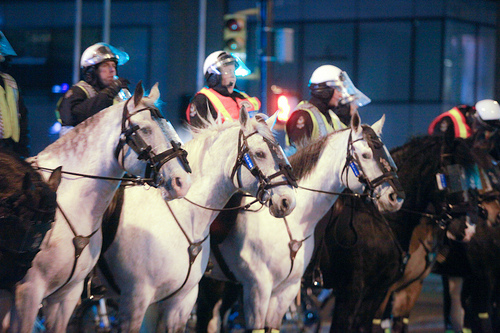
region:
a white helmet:
[78, 40, 133, 68]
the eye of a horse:
[132, 120, 151, 137]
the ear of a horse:
[345, 101, 367, 136]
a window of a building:
[359, 21, 418, 103]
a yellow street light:
[216, 11, 251, 83]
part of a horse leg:
[237, 274, 272, 331]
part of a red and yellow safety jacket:
[430, 106, 470, 138]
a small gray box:
[262, 23, 294, 68]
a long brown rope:
[182, 190, 259, 212]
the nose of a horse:
[277, 193, 289, 211]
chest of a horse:
[263, 235, 306, 279]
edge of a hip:
[353, 267, 371, 293]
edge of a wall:
[424, 56, 448, 96]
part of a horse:
[221, 202, 271, 288]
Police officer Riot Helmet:
[47, 42, 147, 72]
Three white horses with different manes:
[50, 135, 385, 255]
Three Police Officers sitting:
[55, 52, 370, 107]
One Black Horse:
[385, 125, 465, 230]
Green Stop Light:
[205, 5, 285, 75]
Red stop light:
[265, 72, 292, 129]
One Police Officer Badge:
[285, 106, 310, 131]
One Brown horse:
[410, 232, 430, 277]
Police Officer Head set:
[192, 65, 222, 85]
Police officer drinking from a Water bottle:
[98, 80, 143, 101]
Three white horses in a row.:
[25, 80, 402, 332]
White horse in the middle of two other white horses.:
[93, 107, 303, 332]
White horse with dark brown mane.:
[207, 106, 407, 332]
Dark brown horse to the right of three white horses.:
[305, 128, 482, 331]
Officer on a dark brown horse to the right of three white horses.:
[283, 61, 363, 176]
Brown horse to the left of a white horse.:
[0, 143, 65, 288]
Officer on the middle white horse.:
[49, 37, 128, 133]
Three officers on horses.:
[59, 38, 357, 150]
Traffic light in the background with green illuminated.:
[217, 12, 249, 79]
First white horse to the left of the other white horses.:
[2, 80, 194, 332]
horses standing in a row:
[55, 117, 424, 256]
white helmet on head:
[305, 60, 354, 92]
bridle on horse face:
[229, 161, 288, 194]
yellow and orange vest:
[202, 91, 259, 124]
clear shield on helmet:
[332, 78, 374, 110]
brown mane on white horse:
[295, 143, 328, 185]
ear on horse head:
[365, 106, 396, 138]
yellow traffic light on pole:
[219, 7, 266, 64]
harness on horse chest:
[175, 224, 221, 279]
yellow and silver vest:
[304, 112, 339, 136]